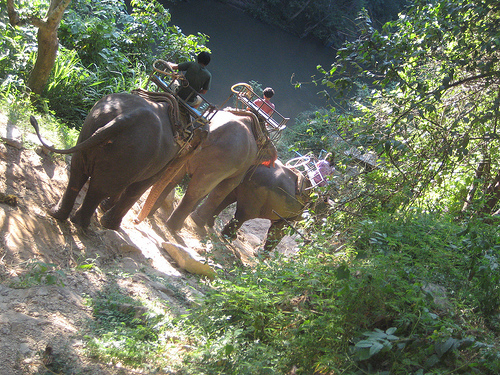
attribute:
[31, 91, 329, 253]
elephants — walking, brown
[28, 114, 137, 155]
tail — up, swinging, gray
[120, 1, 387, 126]
river — black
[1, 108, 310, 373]
dirt — brown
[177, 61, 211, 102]
shirt — green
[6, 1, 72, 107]
trunk — standing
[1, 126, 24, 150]
rock — white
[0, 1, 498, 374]
greenery — thick